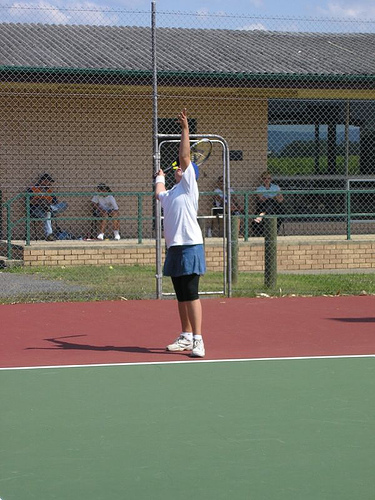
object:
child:
[91, 180, 121, 241]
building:
[0, 21, 373, 266]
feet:
[191, 339, 206, 359]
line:
[0, 352, 374, 370]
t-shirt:
[158, 161, 205, 246]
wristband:
[155, 174, 165, 179]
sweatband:
[151, 173, 167, 185]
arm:
[155, 173, 167, 199]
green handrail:
[242, 187, 372, 245]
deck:
[281, 228, 372, 245]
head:
[174, 160, 198, 183]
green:
[296, 270, 336, 291]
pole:
[197, 189, 373, 193]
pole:
[260, 204, 280, 291]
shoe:
[191, 337, 205, 357]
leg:
[234, 208, 239, 234]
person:
[211, 175, 243, 238]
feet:
[167, 335, 194, 351]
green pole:
[264, 216, 279, 296]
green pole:
[225, 215, 242, 288]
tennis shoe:
[166, 333, 193, 352]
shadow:
[23, 330, 191, 353]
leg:
[179, 244, 202, 339]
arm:
[178, 121, 193, 183]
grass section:
[4, 267, 372, 301]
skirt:
[161, 242, 206, 277]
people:
[26, 171, 70, 237]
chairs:
[25, 200, 118, 238]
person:
[154, 107, 206, 358]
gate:
[150, 120, 200, 233]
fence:
[1, 0, 373, 303]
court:
[0, 296, 373, 498]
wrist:
[155, 175, 165, 185]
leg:
[171, 277, 193, 340]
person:
[90, 180, 122, 239]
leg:
[97, 210, 108, 234]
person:
[254, 170, 284, 235]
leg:
[253, 198, 268, 223]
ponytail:
[98, 181, 112, 193]